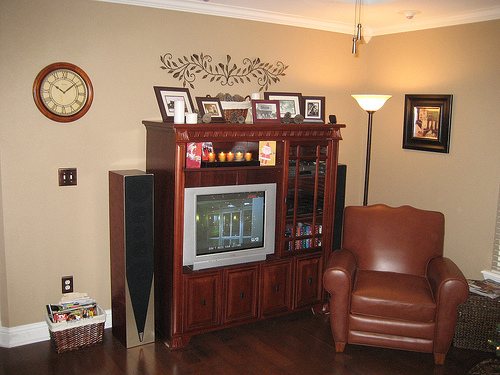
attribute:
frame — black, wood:
[395, 90, 456, 164]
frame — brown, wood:
[28, 60, 93, 124]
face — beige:
[42, 70, 86, 113]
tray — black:
[203, 160, 258, 168]